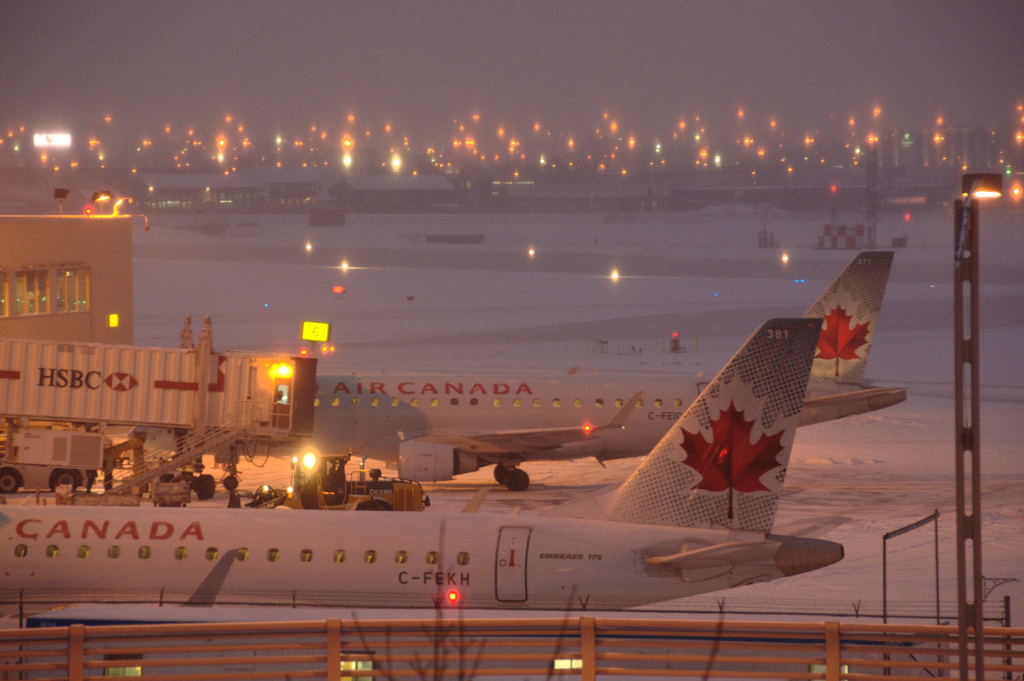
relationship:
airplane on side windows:
[18, 304, 825, 593] [15, 538, 216, 565]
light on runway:
[295, 229, 324, 259] [0, 182, 1022, 609]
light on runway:
[326, 247, 358, 283] [0, 182, 1022, 609]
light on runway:
[772, 245, 795, 269] [0, 182, 1022, 609]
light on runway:
[598, 263, 634, 284] [0, 182, 1022, 609]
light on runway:
[521, 242, 541, 262] [0, 182, 1022, 609]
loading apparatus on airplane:
[20, 333, 386, 468] [247, 238, 934, 496]